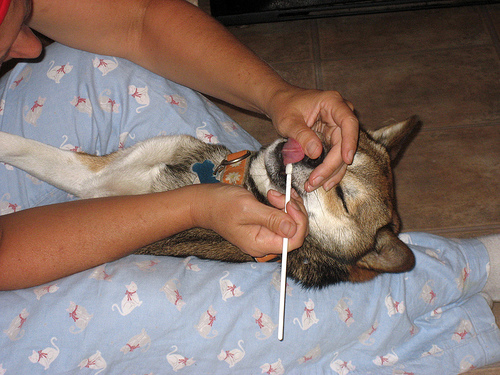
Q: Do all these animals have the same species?
A: No, there are both dogs and cats.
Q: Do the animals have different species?
A: Yes, they are dogs and cats.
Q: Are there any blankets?
A: No, there are no blankets.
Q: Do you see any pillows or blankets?
A: No, there are no blankets or pillows.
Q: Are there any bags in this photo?
A: No, there are no bags.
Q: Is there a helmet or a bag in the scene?
A: No, there are no bags or helmets.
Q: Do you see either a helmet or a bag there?
A: No, there are no bags or helmets.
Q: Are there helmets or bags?
A: No, there are no bags or helmets.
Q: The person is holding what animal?
A: The person is holding the dog.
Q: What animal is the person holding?
A: The person is holding the dog.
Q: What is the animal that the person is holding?
A: The animal is a dog.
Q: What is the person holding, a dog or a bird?
A: The person is holding a dog.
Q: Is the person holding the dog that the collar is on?
A: Yes, the person is holding the dog.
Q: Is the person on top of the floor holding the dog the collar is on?
A: Yes, the person is holding the dog.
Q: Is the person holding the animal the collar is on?
A: Yes, the person is holding the dog.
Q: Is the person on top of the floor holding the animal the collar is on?
A: Yes, the person is holding the dog.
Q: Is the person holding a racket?
A: No, the person is holding the dog.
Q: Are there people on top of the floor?
A: Yes, there is a person on top of the floor.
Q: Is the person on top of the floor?
A: Yes, the person is on top of the floor.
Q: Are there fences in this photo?
A: No, there are no fences.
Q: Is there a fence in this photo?
A: No, there are no fences.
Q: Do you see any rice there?
A: No, there is no rice.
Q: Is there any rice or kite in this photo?
A: No, there are no rice or kites.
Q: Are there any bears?
A: No, there are no bears.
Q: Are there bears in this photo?
A: No, there are no bears.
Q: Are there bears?
A: No, there are no bears.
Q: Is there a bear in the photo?
A: No, there are no bears.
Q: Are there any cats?
A: Yes, there are cats.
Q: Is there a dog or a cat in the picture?
A: Yes, there are cats.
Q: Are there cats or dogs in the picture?
A: Yes, there are cats.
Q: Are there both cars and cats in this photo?
A: No, there are cats but no cars.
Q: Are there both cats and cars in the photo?
A: No, there are cats but no cars.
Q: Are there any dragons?
A: No, there are no dragons.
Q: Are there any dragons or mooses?
A: No, there are no dragons or mooses.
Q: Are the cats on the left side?
A: Yes, the cats are on the left of the image.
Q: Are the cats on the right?
A: No, the cats are on the left of the image.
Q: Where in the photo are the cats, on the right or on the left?
A: The cats are on the left of the image.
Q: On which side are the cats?
A: The cats are on the left of the image.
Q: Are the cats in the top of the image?
A: Yes, the cats are in the top of the image.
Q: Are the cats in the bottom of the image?
A: No, the cats are in the top of the image.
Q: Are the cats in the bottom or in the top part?
A: The cats are in the top of the image.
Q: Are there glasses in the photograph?
A: No, there are no glasses.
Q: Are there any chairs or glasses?
A: No, there are no glasses or chairs.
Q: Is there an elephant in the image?
A: No, there are no elephants.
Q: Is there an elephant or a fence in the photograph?
A: No, there are no elephants or fences.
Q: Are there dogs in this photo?
A: Yes, there is a dog.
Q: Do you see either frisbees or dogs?
A: Yes, there is a dog.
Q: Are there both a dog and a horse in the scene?
A: No, there is a dog but no horses.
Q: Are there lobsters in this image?
A: No, there are no lobsters.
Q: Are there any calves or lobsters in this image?
A: No, there are no lobsters or calves.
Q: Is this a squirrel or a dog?
A: This is a dog.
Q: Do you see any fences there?
A: No, there are no fences.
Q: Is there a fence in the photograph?
A: No, there are no fences.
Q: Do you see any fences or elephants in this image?
A: No, there are no fences or elephants.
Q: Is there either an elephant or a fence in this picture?
A: No, there are no fences or elephants.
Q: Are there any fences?
A: No, there are no fences.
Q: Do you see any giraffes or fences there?
A: No, there are no fences or giraffes.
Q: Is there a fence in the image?
A: No, there are no fences.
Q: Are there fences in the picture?
A: No, there are no fences.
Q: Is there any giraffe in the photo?
A: No, there are no giraffes.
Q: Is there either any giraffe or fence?
A: No, there are no giraffes or fences.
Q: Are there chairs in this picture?
A: No, there are no chairs.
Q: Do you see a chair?
A: No, there are no chairs.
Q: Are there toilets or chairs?
A: No, there are no chairs or toilets.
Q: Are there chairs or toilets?
A: No, there are no chairs or toilets.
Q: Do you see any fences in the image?
A: No, there are no fences.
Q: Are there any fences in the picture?
A: No, there are no fences.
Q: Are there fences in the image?
A: No, there are no fences.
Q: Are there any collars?
A: Yes, there is a collar.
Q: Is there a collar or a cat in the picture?
A: Yes, there is a collar.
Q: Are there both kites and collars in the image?
A: No, there is a collar but no kites.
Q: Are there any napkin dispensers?
A: No, there are no napkin dispensers.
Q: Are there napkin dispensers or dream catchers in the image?
A: No, there are no napkin dispensers or dream catchers.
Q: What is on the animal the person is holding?
A: The collar is on the dog.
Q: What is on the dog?
A: The collar is on the dog.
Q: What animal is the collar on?
A: The collar is on the dog.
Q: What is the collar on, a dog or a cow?
A: The collar is on a dog.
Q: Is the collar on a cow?
A: No, the collar is on the dog.